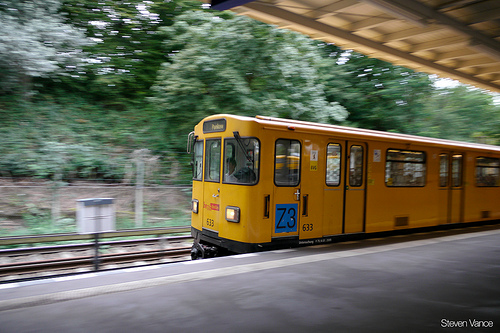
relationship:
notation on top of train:
[274, 201, 298, 232] [181, 102, 498, 242]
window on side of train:
[268, 132, 301, 190] [181, 102, 498, 242]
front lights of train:
[168, 194, 253, 231] [181, 102, 498, 242]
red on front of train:
[202, 203, 224, 217] [181, 102, 498, 242]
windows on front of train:
[190, 140, 256, 185] [181, 102, 498, 242]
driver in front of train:
[224, 159, 254, 181] [181, 102, 498, 242]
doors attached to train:
[320, 133, 368, 235] [181, 102, 498, 242]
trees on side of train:
[157, 27, 317, 114] [181, 102, 498, 242]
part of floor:
[19, 301, 53, 322] [198, 269, 488, 315]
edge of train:
[183, 224, 250, 254] [181, 102, 498, 242]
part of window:
[385, 181, 398, 190] [268, 132, 301, 190]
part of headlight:
[227, 217, 240, 224] [222, 197, 249, 230]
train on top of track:
[181, 102, 498, 242] [3, 241, 197, 270]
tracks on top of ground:
[9, 237, 172, 262] [44, 264, 121, 289]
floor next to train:
[0, 228, 500, 332] [181, 102, 498, 242]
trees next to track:
[157, 27, 317, 114] [3, 241, 197, 270]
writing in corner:
[438, 318, 495, 331] [415, 320, 436, 331]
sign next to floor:
[73, 192, 115, 236] [0, 228, 500, 332]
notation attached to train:
[274, 201, 298, 232] [181, 102, 498, 242]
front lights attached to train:
[189, 199, 241, 225] [181, 102, 498, 242]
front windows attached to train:
[190, 140, 256, 185] [181, 102, 498, 242]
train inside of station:
[181, 102, 498, 242] [240, 27, 479, 329]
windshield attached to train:
[196, 169, 254, 192] [181, 102, 498, 242]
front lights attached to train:
[168, 194, 253, 231] [181, 102, 498, 242]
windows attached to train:
[190, 140, 266, 185] [181, 102, 498, 242]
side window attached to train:
[374, 147, 422, 186] [181, 102, 498, 242]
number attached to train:
[299, 218, 316, 238] [181, 102, 498, 242]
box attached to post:
[73, 192, 115, 236] [76, 235, 119, 254]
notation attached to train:
[269, 194, 291, 224] [181, 102, 498, 242]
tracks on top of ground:
[0, 224, 192, 282] [44, 264, 121, 289]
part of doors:
[342, 223, 357, 231] [320, 133, 368, 235]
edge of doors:
[183, 224, 250, 254] [320, 133, 368, 235]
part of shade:
[353, 37, 377, 46] [337, 0, 492, 82]